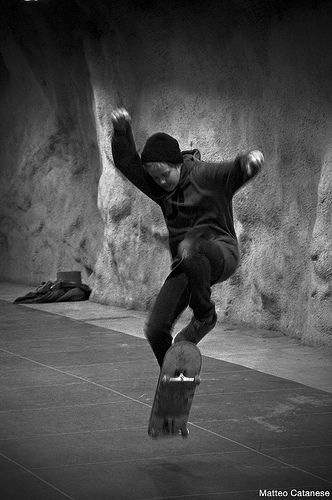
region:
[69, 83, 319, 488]
Young boy skateboarding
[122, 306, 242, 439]
There is a skateboard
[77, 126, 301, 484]
The young boy is jumping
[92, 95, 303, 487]
The young boy is wearing a hat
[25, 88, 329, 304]
There is a wall in the background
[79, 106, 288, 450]
The boy is wearing a black hat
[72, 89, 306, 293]
The boy is wearing a hooded shirt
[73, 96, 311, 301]
The boy has his arms stretched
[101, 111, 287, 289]
the boy is looking down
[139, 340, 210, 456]
skateboard trick in air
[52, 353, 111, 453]
black large tiled floor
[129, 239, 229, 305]
black tight skater jeans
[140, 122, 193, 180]
black skully beanie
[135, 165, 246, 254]
black graphic boys hoodie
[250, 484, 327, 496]
Matteo Catanese white text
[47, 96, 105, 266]
rugged inside of cave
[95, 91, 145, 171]
right hand of boy in air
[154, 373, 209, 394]
silver shiny parts of wheels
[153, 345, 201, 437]
this is a skateboard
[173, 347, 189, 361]
the skateboard is wooden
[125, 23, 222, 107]
this is the wall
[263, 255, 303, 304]
the wall is made of stone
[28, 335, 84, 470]
this is the floor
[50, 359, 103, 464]
the floor is made of stone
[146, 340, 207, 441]
the skateboard is in the air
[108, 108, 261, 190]
the boy's arms are raised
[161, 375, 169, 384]
this is a wheel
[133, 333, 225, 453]
skateboard is brown and mid-air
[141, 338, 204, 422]
skateboard is brown and mid-air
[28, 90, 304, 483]
A young boy skateboading.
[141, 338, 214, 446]
A skateboard in the air.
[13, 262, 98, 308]
A pile of clothes.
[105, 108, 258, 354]
A boy dressed all in dark colors.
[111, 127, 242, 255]
Dark long sleeve shirt.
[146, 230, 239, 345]
A pair of dark pants.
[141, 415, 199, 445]
Back wheels on skateboard.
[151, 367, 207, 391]
Front wheels on skateboard.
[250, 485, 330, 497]
The words Matteo Catanese.